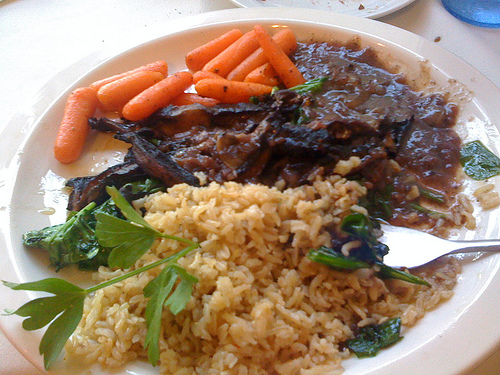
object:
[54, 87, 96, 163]
carrott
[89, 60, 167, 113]
carrott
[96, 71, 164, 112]
carrott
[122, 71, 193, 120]
carrott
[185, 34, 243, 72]
carrott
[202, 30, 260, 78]
carrott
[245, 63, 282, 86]
carrott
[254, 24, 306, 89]
carrott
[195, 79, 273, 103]
carrott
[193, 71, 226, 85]
carrott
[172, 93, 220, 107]
carrott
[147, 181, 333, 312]
rice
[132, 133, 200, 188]
meat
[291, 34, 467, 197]
sauce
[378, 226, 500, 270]
fork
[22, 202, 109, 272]
lettuce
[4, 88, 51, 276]
plate